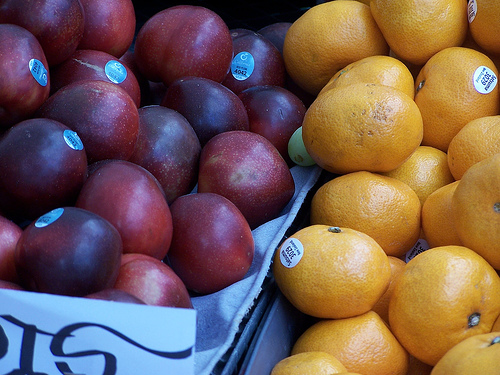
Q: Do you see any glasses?
A: No, there are no glasses.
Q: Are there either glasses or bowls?
A: No, there are no glasses or bowls.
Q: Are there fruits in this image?
A: Yes, there is a fruit.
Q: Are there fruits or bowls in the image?
A: Yes, there is a fruit.